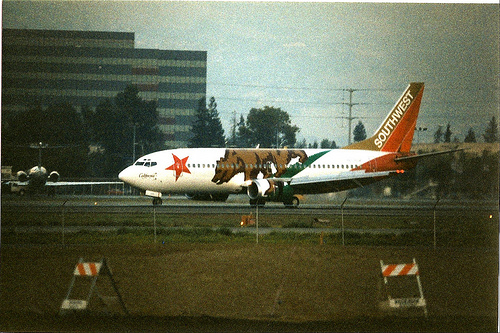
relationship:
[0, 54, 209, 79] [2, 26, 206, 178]
floor of office building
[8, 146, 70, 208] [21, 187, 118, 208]
plane on runway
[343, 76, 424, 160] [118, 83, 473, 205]
tail on plane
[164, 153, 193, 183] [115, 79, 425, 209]
star on plane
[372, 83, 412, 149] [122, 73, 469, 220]
letters on plane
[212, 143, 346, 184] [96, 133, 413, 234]
bear on plane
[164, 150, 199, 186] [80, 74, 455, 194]
star on plane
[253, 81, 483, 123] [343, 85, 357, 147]
three lines on power pole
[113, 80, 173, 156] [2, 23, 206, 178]
trees in front of office building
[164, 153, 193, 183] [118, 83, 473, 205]
star on plane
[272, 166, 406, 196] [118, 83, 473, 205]
wing on side of plane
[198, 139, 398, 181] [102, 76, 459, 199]
windows on side of plane